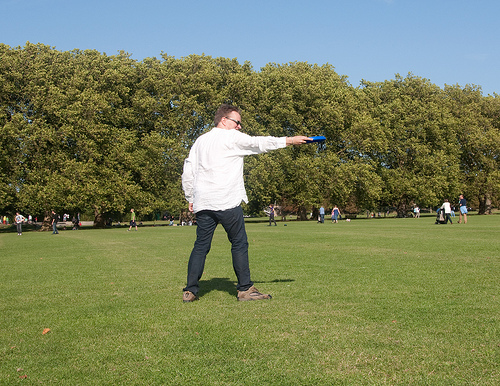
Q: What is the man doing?
A: Playing Frisbee.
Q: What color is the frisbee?
A: Blue.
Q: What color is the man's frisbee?
A: Blue.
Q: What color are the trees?
A: Green.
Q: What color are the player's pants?
A: Black.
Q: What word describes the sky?
A: Clear.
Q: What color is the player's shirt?
A: White.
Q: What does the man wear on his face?
A: Sunglasses.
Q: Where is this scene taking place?
A: Field.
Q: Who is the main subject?
A: Frisbee throwing man.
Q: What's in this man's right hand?
A: Frisbee.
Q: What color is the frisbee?
A: Blue.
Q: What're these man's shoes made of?
A: Suede.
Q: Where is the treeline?
A: At the background.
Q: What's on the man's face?
A: Glasses.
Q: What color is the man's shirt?
A: White.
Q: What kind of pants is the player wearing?
A: Denim.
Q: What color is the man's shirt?
A: White.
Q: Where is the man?
A: A park.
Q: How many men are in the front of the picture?
A: One.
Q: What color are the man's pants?
A: Black.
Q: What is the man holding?
A: A frisbee.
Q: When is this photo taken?
A: Daytime.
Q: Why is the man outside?
A: He is playing frisbee.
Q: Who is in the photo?
A: A man.